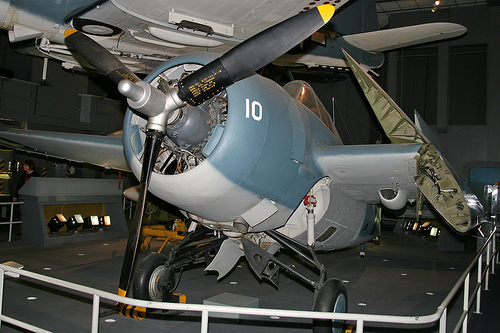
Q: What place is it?
A: It is a display.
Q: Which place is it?
A: It is a display.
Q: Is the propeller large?
A: Yes, the propeller is large.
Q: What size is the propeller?
A: The propeller is large.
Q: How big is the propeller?
A: The propeller is large.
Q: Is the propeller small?
A: No, the propeller is large.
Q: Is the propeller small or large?
A: The propeller is large.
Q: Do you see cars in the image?
A: No, there are no cars.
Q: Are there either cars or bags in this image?
A: No, there are no cars or bags.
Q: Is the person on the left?
A: Yes, the person is on the left of the image.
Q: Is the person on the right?
A: No, the person is on the left of the image.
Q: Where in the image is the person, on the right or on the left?
A: The person is on the left of the image.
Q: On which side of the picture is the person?
A: The person is on the left of the image.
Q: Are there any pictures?
A: No, there are no pictures.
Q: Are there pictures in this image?
A: No, there are no pictures.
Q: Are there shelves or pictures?
A: No, there are no pictures or shelves.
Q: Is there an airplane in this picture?
A: Yes, there is an airplane.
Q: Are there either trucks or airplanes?
A: Yes, there is an airplane.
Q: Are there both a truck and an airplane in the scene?
A: No, there is an airplane but no trucks.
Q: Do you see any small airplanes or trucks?
A: Yes, there is a small airplane.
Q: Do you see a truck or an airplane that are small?
A: Yes, the airplane is small.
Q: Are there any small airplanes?
A: Yes, there is a small airplane.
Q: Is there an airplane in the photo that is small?
A: Yes, there is a small airplane.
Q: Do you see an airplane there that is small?
A: Yes, there is an airplane that is small.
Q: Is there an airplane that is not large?
A: Yes, there is a small airplane.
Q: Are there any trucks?
A: No, there are no trucks.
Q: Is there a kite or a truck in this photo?
A: No, there are no trucks or kites.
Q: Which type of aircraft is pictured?
A: The aircraft is an airplane.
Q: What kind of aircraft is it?
A: The aircraft is an airplane.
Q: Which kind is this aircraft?
A: This is an airplane.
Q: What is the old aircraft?
A: The aircraft is an airplane.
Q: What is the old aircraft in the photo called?
A: The aircraft is an airplane.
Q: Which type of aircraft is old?
A: The aircraft is an airplane.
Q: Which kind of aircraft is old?
A: The aircraft is an airplane.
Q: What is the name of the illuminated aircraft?
A: The aircraft is an airplane.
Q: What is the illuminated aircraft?
A: The aircraft is an airplane.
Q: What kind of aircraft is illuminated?
A: The aircraft is an airplane.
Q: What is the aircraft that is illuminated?
A: The aircraft is an airplane.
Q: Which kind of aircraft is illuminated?
A: The aircraft is an airplane.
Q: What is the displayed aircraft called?
A: The aircraft is an airplane.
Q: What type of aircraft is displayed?
A: The aircraft is an airplane.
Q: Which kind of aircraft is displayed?
A: The aircraft is an airplane.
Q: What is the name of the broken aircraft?
A: The aircraft is an airplane.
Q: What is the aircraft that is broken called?
A: The aircraft is an airplane.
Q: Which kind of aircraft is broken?
A: The aircraft is an airplane.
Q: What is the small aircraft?
A: The aircraft is an airplane.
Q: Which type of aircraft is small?
A: The aircraft is an airplane.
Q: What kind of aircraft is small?
A: The aircraft is an airplane.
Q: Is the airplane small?
A: Yes, the airplane is small.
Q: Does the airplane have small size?
A: Yes, the airplane is small.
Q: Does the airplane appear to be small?
A: Yes, the airplane is small.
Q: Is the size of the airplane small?
A: Yes, the airplane is small.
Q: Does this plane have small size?
A: Yes, the plane is small.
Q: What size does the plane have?
A: The plane has small size.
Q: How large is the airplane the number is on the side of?
A: The airplane is small.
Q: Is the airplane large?
A: No, the airplane is small.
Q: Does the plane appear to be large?
A: No, the plane is small.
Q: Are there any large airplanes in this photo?
A: No, there is an airplane but it is small.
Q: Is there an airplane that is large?
A: No, there is an airplane but it is small.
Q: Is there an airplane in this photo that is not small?
A: No, there is an airplane but it is small.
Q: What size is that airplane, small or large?
A: The airplane is small.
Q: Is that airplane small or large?
A: The airplane is small.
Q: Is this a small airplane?
A: Yes, this is a small airplane.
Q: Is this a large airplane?
A: No, this is a small airplane.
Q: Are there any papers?
A: No, there are no papers.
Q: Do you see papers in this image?
A: No, there are no papers.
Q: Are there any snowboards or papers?
A: No, there are no papers or snowboards.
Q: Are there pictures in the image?
A: No, there are no pictures.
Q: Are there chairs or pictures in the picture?
A: No, there are no pictures or chairs.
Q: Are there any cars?
A: No, there are no cars.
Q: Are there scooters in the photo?
A: No, there are no scooters.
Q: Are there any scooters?
A: No, there are no scooters.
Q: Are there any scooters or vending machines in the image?
A: No, there are no scooters or vending machines.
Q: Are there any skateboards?
A: No, there are no skateboards.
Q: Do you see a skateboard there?
A: No, there are no skateboards.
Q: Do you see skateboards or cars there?
A: No, there are no skateboards or cars.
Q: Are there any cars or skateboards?
A: No, there are no skateboards or cars.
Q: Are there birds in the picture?
A: No, there are no birds.